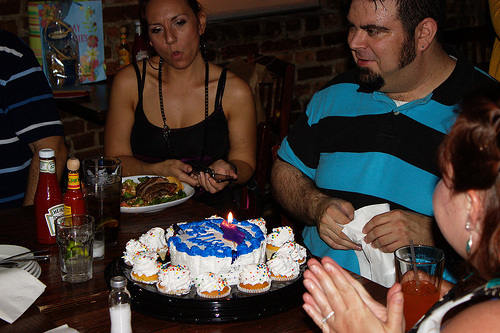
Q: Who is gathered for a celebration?
A: A group.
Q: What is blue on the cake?
A: Frosting.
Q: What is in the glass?
A: Soda.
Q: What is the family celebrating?
A: A birthday.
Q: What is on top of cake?
A: Candle.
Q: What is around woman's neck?
A: Necklace.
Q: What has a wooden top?
A: Hot sauce.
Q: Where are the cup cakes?
A: Around the cake.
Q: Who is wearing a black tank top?
A: Lady wearing necklace.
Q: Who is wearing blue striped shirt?
A: Man with beard.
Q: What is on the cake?
A: A candle.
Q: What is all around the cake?
A: Cupcakes.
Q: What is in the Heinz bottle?
A: Ketchup.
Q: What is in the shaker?
A: Salt.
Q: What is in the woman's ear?
A: A silver earring.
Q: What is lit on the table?
A: A candle.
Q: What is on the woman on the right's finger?
A: A ring.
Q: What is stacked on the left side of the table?
A: Plates.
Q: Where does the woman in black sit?
A: A the table?.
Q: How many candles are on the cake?
A: One.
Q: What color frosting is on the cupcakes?
A: White.